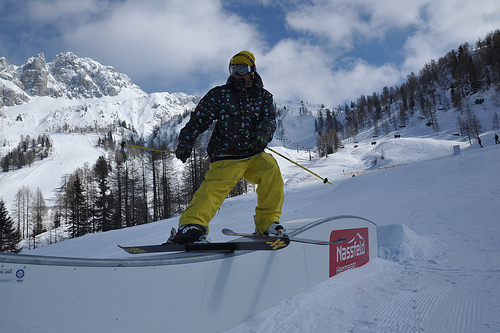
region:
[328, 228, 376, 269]
red promotional logo on slide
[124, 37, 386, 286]
extreme skier on ski slide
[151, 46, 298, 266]
skier wearing yellow pants and hat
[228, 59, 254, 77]
reflective winter goggles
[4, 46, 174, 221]
snow covered mountains and trees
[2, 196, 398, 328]
skiing and snowboarding stunt rail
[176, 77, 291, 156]
multicolored winter skiing coat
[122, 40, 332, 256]
man skiing in yellow winter wear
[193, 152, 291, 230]
bright yellow snow pants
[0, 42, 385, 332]
extreme skier on stunt rail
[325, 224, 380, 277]
red sign covered in snow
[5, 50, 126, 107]
mountainside covered in snow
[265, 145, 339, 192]
yellow metal ski pole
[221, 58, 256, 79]
pair of safety goggles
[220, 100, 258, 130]
design on front of jacket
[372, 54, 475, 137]
trees covered in snow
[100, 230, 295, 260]
black and yellow ski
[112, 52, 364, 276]
man in yellow pants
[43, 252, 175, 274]
silver metal railing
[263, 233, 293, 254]
yellow design on bottom of ski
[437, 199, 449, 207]
part of the snow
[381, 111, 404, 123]
part of a forest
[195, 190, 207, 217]
part of a track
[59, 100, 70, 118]
part of a mountain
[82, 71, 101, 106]
tip of a hill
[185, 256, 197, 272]
part of a board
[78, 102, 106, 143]
part of a slope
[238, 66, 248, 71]
face of a boy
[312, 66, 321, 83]
part of a cloud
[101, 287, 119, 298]
tip of a board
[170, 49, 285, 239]
a man riding on skis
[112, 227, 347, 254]
skis under the man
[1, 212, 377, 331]
a railing for performing tricks on skis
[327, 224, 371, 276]
red logo on the railing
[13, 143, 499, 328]
a snow-covered hill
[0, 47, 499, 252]
hill behind the skier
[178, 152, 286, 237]
yellow pants on the skier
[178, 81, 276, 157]
a ski jacket on the skier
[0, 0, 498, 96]
a cloudy blue sky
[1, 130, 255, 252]
a group of trees behind the skier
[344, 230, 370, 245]
white design on red sign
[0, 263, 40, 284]
sticker on side of guard rail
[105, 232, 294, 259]
black metal ski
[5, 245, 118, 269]
silver metal guard railing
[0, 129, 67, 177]
trees covered in snow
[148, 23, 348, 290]
skier doing trick on rail